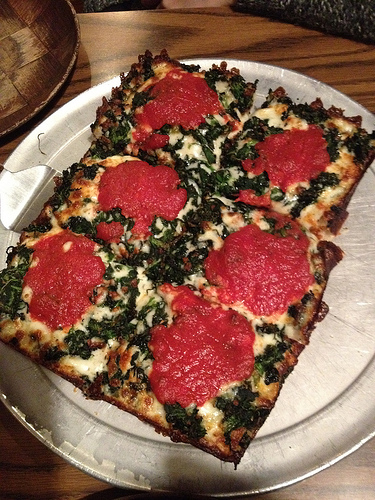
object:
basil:
[200, 170, 239, 201]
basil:
[243, 116, 269, 142]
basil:
[222, 385, 260, 426]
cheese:
[79, 350, 101, 375]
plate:
[0, 57, 375, 500]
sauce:
[202, 209, 315, 317]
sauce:
[20, 229, 105, 333]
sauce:
[231, 123, 333, 208]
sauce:
[95, 160, 187, 244]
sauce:
[131, 68, 225, 151]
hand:
[161, 0, 228, 11]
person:
[164, 0, 375, 43]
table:
[0, 9, 375, 500]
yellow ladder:
[216, 101, 361, 230]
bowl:
[0, 0, 81, 137]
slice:
[211, 85, 375, 228]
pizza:
[0, 48, 375, 473]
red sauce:
[148, 282, 256, 409]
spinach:
[0, 48, 374, 449]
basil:
[147, 226, 198, 286]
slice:
[87, 48, 259, 190]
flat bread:
[0, 48, 375, 471]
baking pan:
[0, 56, 375, 499]